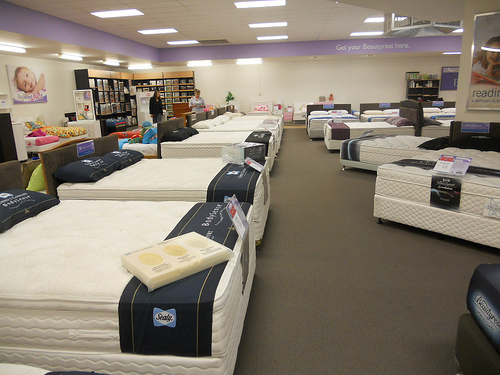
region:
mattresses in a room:
[8, 12, 483, 352]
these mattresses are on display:
[9, 51, 499, 341]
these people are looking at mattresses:
[74, 49, 242, 132]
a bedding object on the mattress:
[109, 226, 256, 296]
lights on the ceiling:
[88, 0, 423, 85]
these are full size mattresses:
[319, 60, 496, 222]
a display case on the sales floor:
[74, 57, 227, 127]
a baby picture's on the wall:
[4, 56, 70, 110]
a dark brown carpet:
[278, 174, 391, 359]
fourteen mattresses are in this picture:
[7, 65, 499, 316]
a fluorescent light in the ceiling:
[87, 4, 154, 25]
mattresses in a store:
[32, 40, 489, 286]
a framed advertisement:
[459, 8, 499, 120]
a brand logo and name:
[144, 308, 180, 330]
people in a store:
[127, 68, 269, 177]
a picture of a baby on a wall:
[2, 60, 50, 105]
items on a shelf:
[79, 66, 196, 122]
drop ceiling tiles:
[172, 3, 234, 40]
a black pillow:
[59, 153, 119, 183]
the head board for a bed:
[40, 135, 118, 177]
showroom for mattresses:
[4, 88, 499, 362]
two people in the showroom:
[148, 89, 205, 121]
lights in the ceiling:
[90, 1, 414, 44]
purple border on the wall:
[2, 5, 468, 55]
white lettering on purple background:
[337, 42, 409, 50]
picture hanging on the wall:
[5, 64, 50, 106]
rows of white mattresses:
[1, 68, 499, 360]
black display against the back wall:
[76, 67, 191, 132]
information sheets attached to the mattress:
[215, 195, 253, 258]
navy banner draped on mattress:
[115, 187, 257, 364]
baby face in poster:
[3, 60, 49, 105]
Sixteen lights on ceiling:
[0, 0, 460, 70]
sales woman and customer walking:
[146, 85, 202, 120]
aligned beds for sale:
[0, 100, 285, 370]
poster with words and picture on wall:
[461, 10, 498, 111]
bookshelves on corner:
[71, 65, 196, 135]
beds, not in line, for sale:
[305, 100, 497, 370]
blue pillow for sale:
[0, 182, 57, 235]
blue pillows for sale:
[55, 146, 145, 181]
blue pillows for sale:
[159, 123, 197, 143]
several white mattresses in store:
[8, 77, 498, 373]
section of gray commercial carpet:
[276, 242, 423, 361]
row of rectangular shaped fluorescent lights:
[83, 6, 205, 54]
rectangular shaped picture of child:
[4, 59, 52, 104]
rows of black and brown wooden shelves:
[76, 61, 193, 127]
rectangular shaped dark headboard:
[36, 134, 123, 191]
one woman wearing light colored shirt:
[186, 89, 203, 110]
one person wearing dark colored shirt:
[149, 89, 164, 119]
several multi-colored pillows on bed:
[23, 119, 85, 148]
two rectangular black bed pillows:
[52, 142, 145, 184]